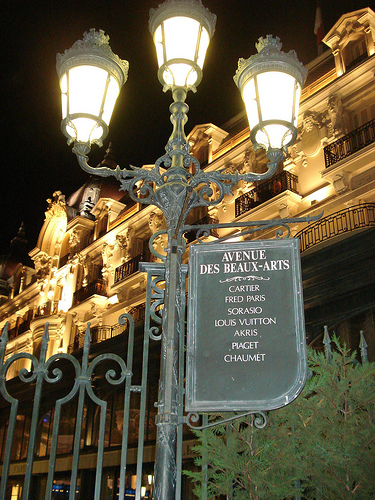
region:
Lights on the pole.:
[42, 3, 346, 203]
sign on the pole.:
[158, 236, 321, 459]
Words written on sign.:
[196, 249, 283, 407]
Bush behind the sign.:
[194, 381, 309, 496]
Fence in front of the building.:
[23, 271, 233, 498]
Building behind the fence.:
[33, 167, 246, 394]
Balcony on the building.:
[98, 258, 152, 298]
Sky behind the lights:
[19, 74, 156, 198]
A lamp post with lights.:
[45, 26, 337, 489]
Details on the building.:
[297, 107, 352, 167]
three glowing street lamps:
[28, 9, 303, 173]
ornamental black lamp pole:
[105, 150, 276, 221]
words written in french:
[193, 243, 293, 274]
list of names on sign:
[209, 281, 279, 368]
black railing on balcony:
[235, 169, 298, 213]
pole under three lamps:
[140, 343, 184, 496]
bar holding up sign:
[184, 211, 329, 244]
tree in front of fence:
[241, 348, 354, 477]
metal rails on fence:
[20, 309, 135, 470]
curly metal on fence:
[92, 349, 127, 389]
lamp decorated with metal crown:
[38, 21, 129, 161]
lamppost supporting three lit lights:
[60, 8, 289, 218]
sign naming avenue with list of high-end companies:
[161, 206, 314, 409]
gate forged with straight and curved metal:
[8, 285, 146, 487]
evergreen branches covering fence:
[190, 300, 363, 480]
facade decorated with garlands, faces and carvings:
[276, 90, 342, 200]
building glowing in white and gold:
[16, 186, 174, 337]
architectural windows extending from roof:
[56, 187, 141, 258]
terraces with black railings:
[75, 147, 366, 274]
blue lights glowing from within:
[31, 408, 146, 493]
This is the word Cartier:
[224, 280, 265, 293]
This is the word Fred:
[224, 291, 247, 304]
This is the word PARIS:
[244, 289, 270, 301]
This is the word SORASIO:
[227, 301, 265, 316]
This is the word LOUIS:
[209, 316, 237, 328]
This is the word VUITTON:
[238, 315, 278, 327]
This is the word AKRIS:
[234, 323, 260, 338]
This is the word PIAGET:
[224, 338, 264, 353]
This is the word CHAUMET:
[219, 349, 272, 370]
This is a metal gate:
[12, 317, 147, 491]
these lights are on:
[49, 8, 309, 184]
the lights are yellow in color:
[58, 16, 303, 154]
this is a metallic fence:
[7, 329, 156, 498]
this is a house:
[310, 27, 363, 199]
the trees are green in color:
[239, 431, 356, 492]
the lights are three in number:
[59, 0, 295, 176]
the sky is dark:
[2, 1, 55, 194]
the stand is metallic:
[85, 160, 272, 240]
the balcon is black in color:
[252, 178, 291, 198]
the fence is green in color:
[6, 311, 177, 489]